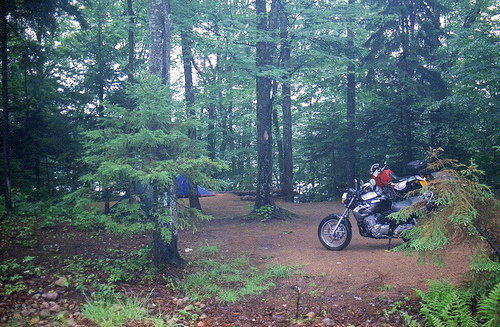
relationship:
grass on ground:
[69, 234, 320, 325] [1, 191, 498, 323]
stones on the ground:
[37, 291, 62, 315] [76, 230, 408, 296]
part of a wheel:
[322, 215, 337, 249] [292, 194, 379, 266]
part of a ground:
[236, 287, 406, 327] [388, 127, 413, 152]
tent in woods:
[110, 171, 215, 208] [3, 3, 495, 218]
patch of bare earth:
[184, 228, 424, 274] [176, 185, 472, 281]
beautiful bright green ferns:
[252, 128, 472, 267] [404, 262, 497, 319]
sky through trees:
[92, 51, 438, 180] [2, 1, 494, 149]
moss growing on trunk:
[74, 76, 272, 218] [250, 147, 292, 198]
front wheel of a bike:
[304, 211, 354, 267] [318, 154, 443, 249]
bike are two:
[318, 154, 443, 249] [69, 123, 464, 309]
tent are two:
[110, 171, 215, 208] [69, 126, 238, 304]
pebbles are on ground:
[0, 258, 431, 327] [1, 191, 498, 323]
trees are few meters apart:
[54, 12, 363, 143] [122, 192, 208, 275]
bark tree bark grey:
[257, 52, 278, 198] [157, 207, 247, 327]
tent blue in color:
[110, 171, 215, 208] [148, 138, 233, 264]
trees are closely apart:
[2, 0, 76, 280] [80, 255, 166, 281]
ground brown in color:
[1, 191, 498, 323] [72, 201, 440, 327]